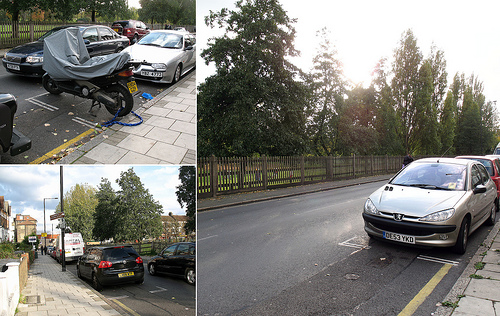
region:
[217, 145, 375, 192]
Fences surrounding a steet.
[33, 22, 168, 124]
A cover covering a motorcycle.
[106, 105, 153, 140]
A blue cord attached to a tired.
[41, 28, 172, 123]
A motorcycle parked in front of a car.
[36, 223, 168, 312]
Cars parked near a street.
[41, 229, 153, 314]
Cars parked near a sidewalk.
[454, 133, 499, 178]
A red car parked behind a silver car.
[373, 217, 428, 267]
License plate hanging in front of a car.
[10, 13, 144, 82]
A car driving pass a silver car.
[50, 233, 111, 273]
A white truck parked in front of a black car.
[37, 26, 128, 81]
a grey cover on a motorcycle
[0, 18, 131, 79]
a black car on a road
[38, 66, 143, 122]
a black and grey motorcycle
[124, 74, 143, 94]
a yelow license plate on a motorcycle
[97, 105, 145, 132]
a blue rope tying a motorcycle down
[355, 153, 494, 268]
a gray car parked alongside a road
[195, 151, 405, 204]
a wooden fence alongside a road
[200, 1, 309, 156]
a green tree behind a fence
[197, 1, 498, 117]
a grey sky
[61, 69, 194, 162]
a concrete sidewalk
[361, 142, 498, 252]
the parked cars on the road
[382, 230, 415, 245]
the license plate on the car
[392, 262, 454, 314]
the yellow line on the road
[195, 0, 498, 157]
the trees on the side of the road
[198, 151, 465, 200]
the fence on the side of the road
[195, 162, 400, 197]
the green grass on the other side of the fence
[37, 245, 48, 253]
the people on the sidewalk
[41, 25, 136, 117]
the parked motorcycle on the road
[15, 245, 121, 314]
the sidewalk next to the road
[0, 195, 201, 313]
the buildings in the area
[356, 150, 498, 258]
vehicle parked on a street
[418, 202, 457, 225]
front headlight on a vehicle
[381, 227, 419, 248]
front licence plate on a vehicle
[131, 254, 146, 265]
rear tail light on a vehicle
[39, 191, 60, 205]
street light on a pole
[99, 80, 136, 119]
rear wheel on a motorcycle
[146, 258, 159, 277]
front wheel on a vehicle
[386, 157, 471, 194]
front windshield on a vehicle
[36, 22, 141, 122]
motorcycle parked on a street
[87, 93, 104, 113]
kickstand on a motorcycle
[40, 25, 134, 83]
a gray cover on a motorcycle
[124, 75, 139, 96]
a yellow license plate on a motorcycle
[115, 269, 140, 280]
a license plate on a car